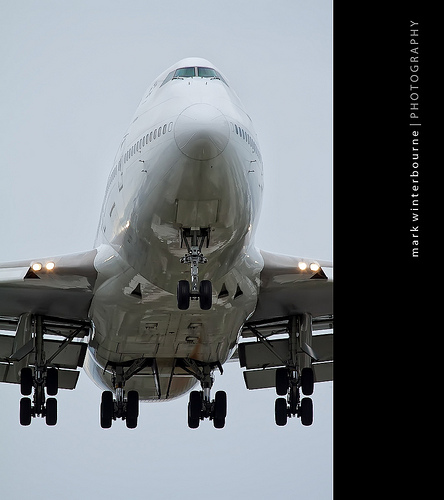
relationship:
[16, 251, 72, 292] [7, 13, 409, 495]
lights on each airplane wing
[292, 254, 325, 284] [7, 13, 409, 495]
lights on each airplane wing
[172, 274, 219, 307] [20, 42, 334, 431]
wheels are attached to plane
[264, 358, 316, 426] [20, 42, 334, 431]
wheels are attached to plane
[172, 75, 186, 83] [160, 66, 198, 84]
wiper on window